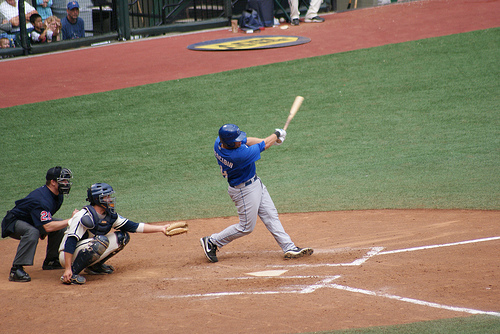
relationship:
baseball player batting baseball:
[199, 94, 315, 259] [301, 70, 329, 102]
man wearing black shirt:
[2, 162, 80, 283] [0, 185, 67, 228]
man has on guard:
[2, 162, 80, 283] [55, 165, 72, 195]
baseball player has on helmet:
[198, 122, 318, 264] [216, 121, 248, 143]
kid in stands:
[26, 11, 65, 52] [9, 1, 230, 56]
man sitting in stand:
[57, 2, 89, 40] [2, 0, 397, 50]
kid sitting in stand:
[26, 11, 62, 46] [2, 0, 397, 50]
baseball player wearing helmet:
[198, 122, 318, 264] [216, 121, 246, 146]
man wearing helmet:
[2, 162, 79, 280] [43, 164, 70, 181]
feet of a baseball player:
[199, 233, 314, 263] [198, 122, 318, 264]